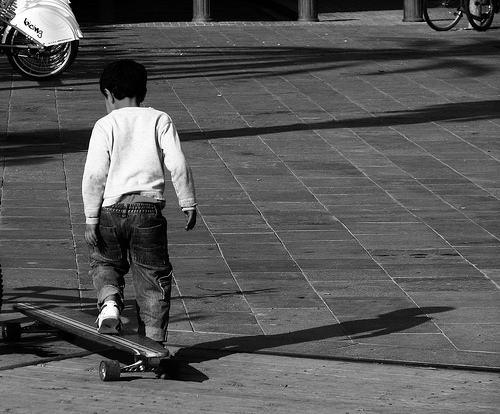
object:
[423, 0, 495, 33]
bicycle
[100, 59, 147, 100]
hair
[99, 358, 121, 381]
wheel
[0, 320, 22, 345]
wheel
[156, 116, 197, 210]
sleeve shirt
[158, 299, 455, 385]
shadow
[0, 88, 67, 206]
ground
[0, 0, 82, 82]
motorbike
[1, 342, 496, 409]
walkway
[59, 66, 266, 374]
boy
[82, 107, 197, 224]
sweater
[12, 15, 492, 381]
wrong picture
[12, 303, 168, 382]
skateboard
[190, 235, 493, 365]
ground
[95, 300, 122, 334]
shoe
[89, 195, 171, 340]
jeans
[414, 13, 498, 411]
right